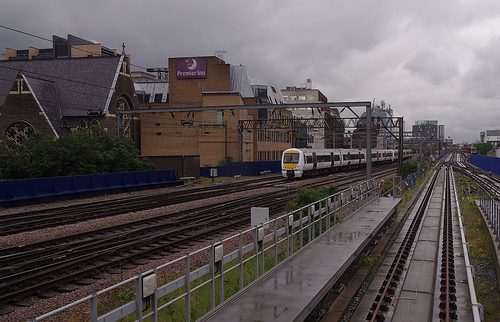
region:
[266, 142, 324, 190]
Yellow front on train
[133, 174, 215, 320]
Train on tracks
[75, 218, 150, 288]
Gravel near sides of tracks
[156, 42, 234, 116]
Purple sign on building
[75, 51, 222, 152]
Brick building near train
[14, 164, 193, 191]
Blue barrier near tracks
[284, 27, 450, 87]
Sky is gray and overcast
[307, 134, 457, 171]
train is mostly white in color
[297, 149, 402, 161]
Many windows on the side of the train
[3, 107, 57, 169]
Decorative window on side of building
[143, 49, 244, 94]
Premier Inn sign above railway.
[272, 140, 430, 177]
Passenger train on train tracks.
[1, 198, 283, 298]
Train tracks parallel to each other.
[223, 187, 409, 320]
Bench sitting next to trolley tracks.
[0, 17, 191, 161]
Church next to hotel.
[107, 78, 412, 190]
Train signal overhang above train tracks.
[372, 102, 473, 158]
Large building in background.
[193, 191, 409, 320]
Bench with puddles of water after a rain shower.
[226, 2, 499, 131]
Overcast sky with grey clouds.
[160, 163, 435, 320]
Strip of grass between train track and trolley track.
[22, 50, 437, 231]
white train with yellow on front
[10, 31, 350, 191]
buildings for different purposes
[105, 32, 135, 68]
small cross on top of roof edge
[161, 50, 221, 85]
large purple sign on tan building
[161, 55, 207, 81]
graphic of a partial moon and star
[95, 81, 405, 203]
metal spans across the tracks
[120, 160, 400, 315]
silver railing along a platform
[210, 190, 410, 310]
puddles formed on platform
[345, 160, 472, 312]
straight track next to platform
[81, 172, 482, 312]
traditional train tracks near modern train tracks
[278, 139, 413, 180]
White train on the tracks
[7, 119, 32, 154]
Circular window on triangular building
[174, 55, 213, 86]
Purple sing on the tallest building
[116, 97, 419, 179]
Structures over the train tracks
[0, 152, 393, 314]
two sets of train tracks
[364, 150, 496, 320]
Tracks that have concrete below them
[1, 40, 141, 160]
The church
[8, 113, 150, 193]
The trees in front of the church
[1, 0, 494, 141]
The clouds in the sky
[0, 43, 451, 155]
The row of buildings next to the tracks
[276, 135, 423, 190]
commuter train on tracks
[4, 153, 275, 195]
blue retaining wall beside tracks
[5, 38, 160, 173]
church beside train track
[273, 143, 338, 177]
white and yellow train car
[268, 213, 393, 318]
rain puddles on platform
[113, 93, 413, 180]
overhead signals on tracks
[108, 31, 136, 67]
cross on top of church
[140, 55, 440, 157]
tall buildings beside tracks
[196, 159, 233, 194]
sign standing beside tracks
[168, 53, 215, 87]
purple sign on building